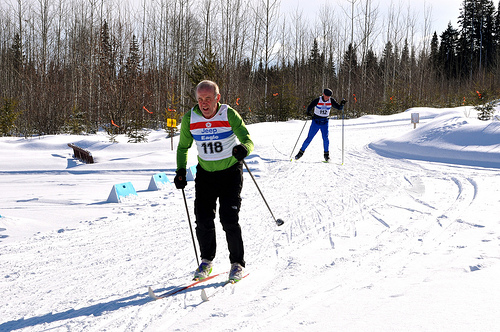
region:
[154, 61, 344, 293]
Two persons are skating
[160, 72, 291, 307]
Skier is old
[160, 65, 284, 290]
Skier is number 118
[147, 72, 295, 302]
Skier wears green sweter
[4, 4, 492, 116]
Trees behind the snow trail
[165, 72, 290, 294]
Skier wears black pants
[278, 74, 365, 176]
Skier has blue pants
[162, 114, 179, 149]
Yellow sign on pole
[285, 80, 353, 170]
Skier wears a white vest with a number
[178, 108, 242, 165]
Vest has red and blue stripes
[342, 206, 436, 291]
ground is white in color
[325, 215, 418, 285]
snow is in ground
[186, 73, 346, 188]
two people are skiing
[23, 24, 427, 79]
trees are behind them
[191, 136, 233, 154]
number on his coat is 118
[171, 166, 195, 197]
gloves is black in color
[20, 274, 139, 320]
shadow falls on the ground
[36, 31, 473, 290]
daytime picture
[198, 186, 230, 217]
pant is black in color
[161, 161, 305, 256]
he has skiing poles in hand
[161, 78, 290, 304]
an older man cross country skiing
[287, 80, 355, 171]
another older man cross country skiing in the distance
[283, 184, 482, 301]
snowy ground covered in ski tracks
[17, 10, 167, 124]
many thin bare trees in the forest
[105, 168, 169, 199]
light blue trail markers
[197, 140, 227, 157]
the man's black race number on his jacket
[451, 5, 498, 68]
a large pine tree in the forest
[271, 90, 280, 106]
an orange flag to mark the trail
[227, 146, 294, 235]
the man's ski pole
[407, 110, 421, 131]
a small white sign on the trail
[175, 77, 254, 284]
A man with green shirt and black pant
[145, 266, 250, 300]
a set of show skis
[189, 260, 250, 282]
A pair of gray and white shoes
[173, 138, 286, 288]
a pair of black ski sticks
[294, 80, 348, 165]
A man with black sweater and blue pants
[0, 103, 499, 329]
lots of beautiful white snow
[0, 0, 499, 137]
a line of trees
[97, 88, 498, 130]
orange ribbons tied on trees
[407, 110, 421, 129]
a white and brown sign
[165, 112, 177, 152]
a pole with a yellow sign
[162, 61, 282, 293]
Old man skiing on the snow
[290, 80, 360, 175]
Person wearing a white vest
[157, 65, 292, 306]
Old man wearing a vest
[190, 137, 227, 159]
Number 118 on vest of old man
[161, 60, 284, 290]
Man wearing a green longs sleeve shirt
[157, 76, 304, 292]
Man wearing black pants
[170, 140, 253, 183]
Gloves are black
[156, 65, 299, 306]
Man holding two snow poles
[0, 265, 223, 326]
Shadow of man casting on the snow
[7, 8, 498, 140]
Trees on the background